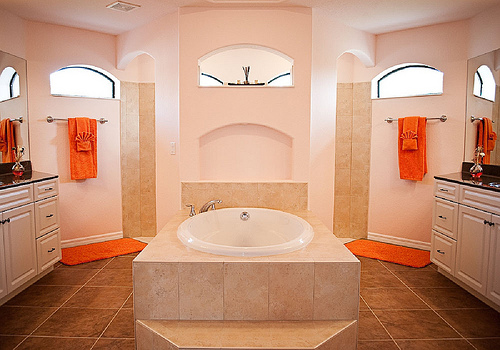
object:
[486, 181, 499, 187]
sink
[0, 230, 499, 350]
ground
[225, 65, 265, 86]
light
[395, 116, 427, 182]
towels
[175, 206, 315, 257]
tub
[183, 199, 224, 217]
faucet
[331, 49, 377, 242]
doors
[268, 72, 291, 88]
window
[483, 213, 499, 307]
cabinets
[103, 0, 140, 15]
vent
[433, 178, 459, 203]
drawer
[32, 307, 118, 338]
tiles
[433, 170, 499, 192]
countertop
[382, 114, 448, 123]
rack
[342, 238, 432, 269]
rug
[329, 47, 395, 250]
doorway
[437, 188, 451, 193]
handle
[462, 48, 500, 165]
mirror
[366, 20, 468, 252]
wall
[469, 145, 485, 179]
vase